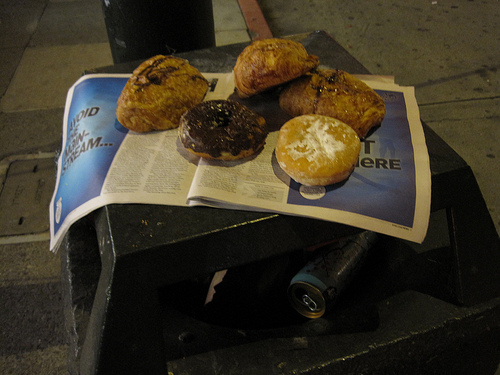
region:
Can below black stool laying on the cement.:
[281, 247, 401, 338]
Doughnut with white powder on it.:
[277, 110, 362, 190]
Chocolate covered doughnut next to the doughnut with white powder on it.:
[178, 92, 270, 165]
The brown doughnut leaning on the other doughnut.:
[228, 35, 324, 98]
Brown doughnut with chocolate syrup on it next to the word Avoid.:
[113, 48, 209, 135]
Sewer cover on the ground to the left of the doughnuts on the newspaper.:
[7, 155, 55, 247]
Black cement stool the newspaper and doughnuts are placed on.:
[47, 113, 498, 325]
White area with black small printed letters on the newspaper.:
[132, 126, 289, 203]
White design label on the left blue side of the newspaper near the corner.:
[53, 197, 67, 225]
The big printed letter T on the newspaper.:
[359, 137, 384, 154]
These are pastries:
[107, 24, 367, 221]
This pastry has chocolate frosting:
[177, 95, 267, 199]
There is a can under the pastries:
[260, 212, 443, 331]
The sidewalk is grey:
[11, 12, 131, 346]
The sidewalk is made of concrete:
[34, 0, 94, 346]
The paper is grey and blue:
[52, 49, 152, 269]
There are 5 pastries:
[104, 28, 392, 199]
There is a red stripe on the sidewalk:
[203, 2, 328, 55]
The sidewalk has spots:
[327, 2, 494, 79]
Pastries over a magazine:
[116, 30, 383, 190]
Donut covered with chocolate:
[172, 87, 267, 162]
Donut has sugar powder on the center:
[275, 111, 363, 187]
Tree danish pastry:
[101, 21, 396, 131]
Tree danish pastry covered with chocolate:
[111, 24, 388, 125]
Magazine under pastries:
[30, 58, 440, 248]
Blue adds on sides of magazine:
[43, 55, 443, 242]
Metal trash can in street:
[40, 7, 498, 372]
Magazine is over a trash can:
[42, 65, 432, 256]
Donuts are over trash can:
[106, 24, 393, 199]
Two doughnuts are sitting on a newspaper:
[181, 101, 365, 193]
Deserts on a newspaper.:
[70, 60, 425, 252]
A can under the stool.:
[287, 253, 417, 318]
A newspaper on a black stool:
[36, 87, 496, 297]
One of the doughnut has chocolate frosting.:
[182, 90, 259, 185]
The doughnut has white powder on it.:
[281, 120, 367, 208]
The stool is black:
[45, 228, 496, 374]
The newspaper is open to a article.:
[51, 87, 426, 246]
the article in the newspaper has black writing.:
[34, 72, 174, 226]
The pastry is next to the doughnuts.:
[226, 36, 398, 134]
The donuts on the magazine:
[114, 31, 384, 188]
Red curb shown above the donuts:
[230, 0, 282, 53]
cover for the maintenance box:
[1, 150, 61, 246]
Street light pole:
[95, 1, 221, 66]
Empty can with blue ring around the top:
[286, 218, 376, 324]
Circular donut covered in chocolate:
[177, 97, 266, 163]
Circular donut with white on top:
[274, 110, 364, 185]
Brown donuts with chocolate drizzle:
[116, 35, 389, 134]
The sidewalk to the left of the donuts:
[0, 0, 275, 371]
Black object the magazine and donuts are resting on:
[55, 28, 490, 372]